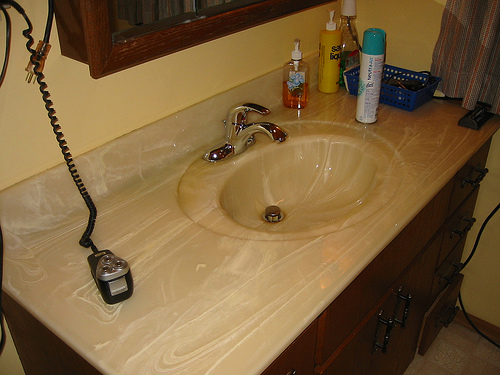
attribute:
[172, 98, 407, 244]
bathroom sink — tan